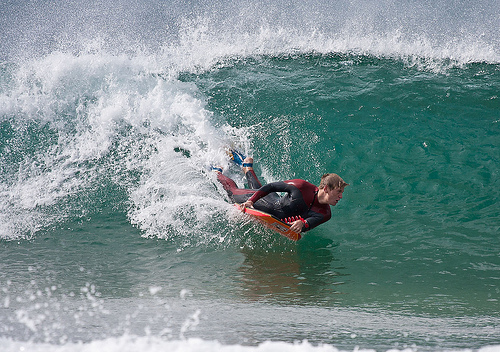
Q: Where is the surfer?
A: In the ocean.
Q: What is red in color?
A: Surfboard.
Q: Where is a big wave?
A: In the ocean.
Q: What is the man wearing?
A: A wetsuit.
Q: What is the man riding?
A: A wave.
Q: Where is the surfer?
A: On a surfboard in the ocean.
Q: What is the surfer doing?
A: Surfing.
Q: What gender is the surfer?
A: Male.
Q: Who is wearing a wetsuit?
A: The surfer.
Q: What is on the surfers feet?
A: Flippers.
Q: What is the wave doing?
A: Cresting.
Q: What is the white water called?
A: Wave crests.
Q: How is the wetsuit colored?
A: Black and red.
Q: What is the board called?
A: A boogie board.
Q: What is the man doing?
A: Surfing.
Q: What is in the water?
A: A man.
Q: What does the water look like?
A: Clear.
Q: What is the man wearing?
A: A wetsuit.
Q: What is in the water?
A: Waves.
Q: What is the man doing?
A: Surfing.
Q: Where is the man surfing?
A: In the ocean.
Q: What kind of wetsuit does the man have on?
A: Red and black.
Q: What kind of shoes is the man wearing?
A: Flippers.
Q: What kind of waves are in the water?
A: White.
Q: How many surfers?
A: One.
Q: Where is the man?
A: In the water.